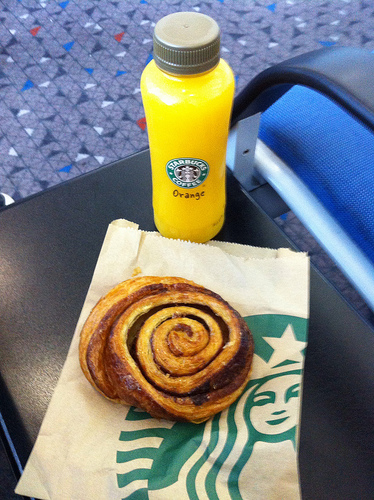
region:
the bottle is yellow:
[136, 44, 239, 241]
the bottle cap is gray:
[137, 8, 231, 79]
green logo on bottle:
[161, 149, 208, 187]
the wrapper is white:
[20, 201, 319, 498]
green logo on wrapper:
[6, 206, 323, 497]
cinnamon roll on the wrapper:
[74, 276, 291, 435]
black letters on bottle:
[159, 179, 214, 205]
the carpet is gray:
[4, 6, 372, 202]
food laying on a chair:
[1, 29, 372, 498]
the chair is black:
[1, 36, 372, 496]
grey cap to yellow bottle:
[148, 8, 223, 74]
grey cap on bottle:
[148, 11, 218, 76]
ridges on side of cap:
[167, 45, 197, 65]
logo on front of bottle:
[157, 157, 214, 196]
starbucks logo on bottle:
[164, 157, 209, 193]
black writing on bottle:
[172, 189, 207, 201]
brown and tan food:
[92, 267, 239, 428]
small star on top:
[261, 318, 311, 375]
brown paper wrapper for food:
[258, 250, 305, 318]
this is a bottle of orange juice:
[128, 10, 277, 236]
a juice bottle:
[128, 13, 279, 256]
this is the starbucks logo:
[153, 145, 225, 193]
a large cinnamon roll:
[73, 255, 264, 427]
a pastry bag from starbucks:
[3, 221, 339, 498]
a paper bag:
[1, 225, 342, 497]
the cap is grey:
[133, 6, 239, 74]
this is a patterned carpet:
[22, 10, 144, 109]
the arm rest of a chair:
[241, 6, 372, 181]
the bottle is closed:
[121, 0, 265, 263]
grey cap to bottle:
[155, 1, 223, 70]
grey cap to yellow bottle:
[155, 5, 222, 75]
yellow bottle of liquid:
[154, 67, 235, 250]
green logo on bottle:
[155, 146, 215, 207]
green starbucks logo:
[159, 156, 210, 203]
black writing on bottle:
[161, 182, 206, 206]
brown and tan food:
[108, 278, 247, 401]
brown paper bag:
[216, 244, 303, 305]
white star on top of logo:
[260, 321, 307, 372]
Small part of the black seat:
[330, 403, 372, 439]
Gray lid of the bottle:
[155, 11, 216, 51]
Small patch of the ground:
[40, 30, 100, 89]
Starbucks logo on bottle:
[164, 154, 208, 186]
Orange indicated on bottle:
[171, 187, 206, 201]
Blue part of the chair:
[322, 143, 354, 184]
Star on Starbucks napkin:
[263, 320, 305, 367]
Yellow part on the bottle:
[178, 112, 199, 132]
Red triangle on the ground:
[113, 29, 127, 45]